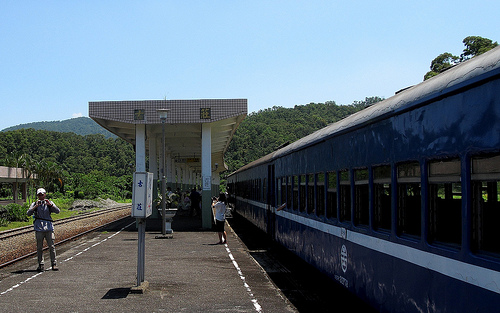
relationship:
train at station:
[221, 38, 499, 311] [7, 89, 339, 311]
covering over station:
[89, 96, 253, 163] [0, 98, 300, 312]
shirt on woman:
[210, 199, 227, 220] [205, 192, 232, 244]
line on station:
[220, 237, 265, 312] [0, 98, 300, 312]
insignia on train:
[331, 238, 355, 285] [221, 38, 499, 311]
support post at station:
[197, 119, 216, 232] [7, 89, 339, 311]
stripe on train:
[224, 186, 500, 293] [221, 38, 499, 311]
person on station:
[186, 185, 204, 220] [7, 89, 339, 311]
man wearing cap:
[23, 183, 66, 272] [33, 186, 51, 195]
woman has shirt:
[205, 192, 232, 244] [210, 199, 227, 220]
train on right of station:
[221, 38, 499, 311] [0, 98, 300, 312]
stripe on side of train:
[224, 186, 500, 293] [221, 38, 499, 311]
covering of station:
[89, 96, 253, 163] [0, 98, 300, 312]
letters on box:
[134, 178, 145, 213] [130, 169, 156, 219]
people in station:
[161, 181, 200, 217] [0, 98, 300, 312]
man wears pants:
[23, 183, 66, 272] [34, 224, 63, 264]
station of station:
[0, 98, 300, 312] [7, 89, 339, 311]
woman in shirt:
[205, 192, 232, 244] [210, 199, 227, 220]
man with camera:
[23, 183, 66, 272] [36, 197, 51, 207]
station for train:
[7, 89, 339, 311] [221, 38, 499, 311]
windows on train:
[276, 153, 500, 266] [221, 38, 499, 311]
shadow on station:
[96, 280, 135, 303] [0, 98, 300, 312]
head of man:
[33, 185, 49, 202] [23, 183, 66, 272]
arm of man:
[44, 195, 63, 214] [23, 183, 66, 272]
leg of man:
[44, 218, 61, 271] [23, 183, 66, 272]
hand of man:
[44, 198, 52, 205] [23, 183, 66, 272]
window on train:
[369, 155, 395, 240] [221, 38, 499, 311]